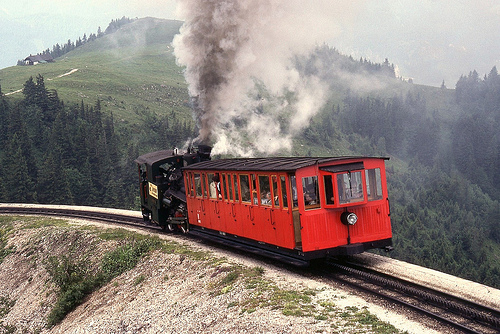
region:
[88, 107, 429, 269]
the train is in motion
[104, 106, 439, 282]
the train car is red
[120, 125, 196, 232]
the conductors car is black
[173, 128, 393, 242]
passengers are on the train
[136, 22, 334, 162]
smoke is coming from the train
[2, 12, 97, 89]
a house in the background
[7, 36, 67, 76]
the house is white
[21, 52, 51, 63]
the roof of the house is black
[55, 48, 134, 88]
the road going up the hill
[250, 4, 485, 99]
the sky is overcast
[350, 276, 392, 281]
A single rail track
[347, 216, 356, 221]
Light in the center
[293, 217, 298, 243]
Door of coach open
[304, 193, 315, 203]
A person seated down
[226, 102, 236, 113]
White smoke in the air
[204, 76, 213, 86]
Black smoke in the air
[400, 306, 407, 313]
Stones alongside the rail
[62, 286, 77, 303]
Grass running down the slope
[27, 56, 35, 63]
A building on the hill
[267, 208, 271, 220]
A handle on the coach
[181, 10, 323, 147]
steams in the sky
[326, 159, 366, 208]
windows on a train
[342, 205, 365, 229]
the front light of a train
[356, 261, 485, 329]
rails of a train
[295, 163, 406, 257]
front of a train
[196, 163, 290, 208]
windows of a train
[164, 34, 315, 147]
steam coming from train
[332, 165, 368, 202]
windshield of a train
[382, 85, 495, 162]
trees and grasses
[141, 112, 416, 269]
a red train passing by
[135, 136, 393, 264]
red and black train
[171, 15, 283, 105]
brown smoke from train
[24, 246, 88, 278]
short green and brown grass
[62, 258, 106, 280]
short green and brown grass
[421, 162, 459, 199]
short green and brown grass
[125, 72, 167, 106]
short green and brown grass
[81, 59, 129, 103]
short green and brown grass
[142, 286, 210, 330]
short green and brown grass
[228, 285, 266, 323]
short green and brown grass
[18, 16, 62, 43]
white clouds in blue sky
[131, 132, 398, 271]
red train car and engine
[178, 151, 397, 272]
red train car with people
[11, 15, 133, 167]
hillside with trees and grass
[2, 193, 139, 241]
curved section of railroad track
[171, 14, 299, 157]
grey and white smoke in front of grass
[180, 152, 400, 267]
red rail car with black roof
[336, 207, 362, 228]
rail car headlight on red car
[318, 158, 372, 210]
window with red border and black roof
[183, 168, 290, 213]
windows of red passenger rail car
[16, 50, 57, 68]
house on distant hillside